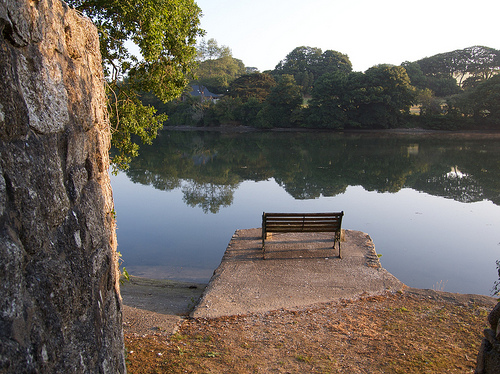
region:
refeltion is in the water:
[255, 146, 475, 208]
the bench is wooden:
[253, 206, 360, 266]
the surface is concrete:
[235, 261, 371, 296]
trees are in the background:
[283, 63, 398, 123]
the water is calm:
[285, 140, 430, 222]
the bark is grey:
[35, 105, 111, 340]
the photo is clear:
[2, 11, 482, 352]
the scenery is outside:
[2, 5, 487, 367]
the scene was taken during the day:
[6, 5, 476, 366]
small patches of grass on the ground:
[292, 312, 418, 359]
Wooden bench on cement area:
[258, 208, 345, 258]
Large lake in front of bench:
[114, 130, 498, 290]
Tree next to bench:
[68, 0, 202, 173]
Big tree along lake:
[264, 73, 306, 120]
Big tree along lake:
[310, 73, 351, 105]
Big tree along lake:
[345, 70, 385, 101]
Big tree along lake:
[368, 62, 415, 114]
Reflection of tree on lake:
[180, 127, 238, 210]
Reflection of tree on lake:
[440, 171, 487, 201]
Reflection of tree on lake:
[147, 132, 179, 189]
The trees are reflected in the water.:
[121, 39, 496, 211]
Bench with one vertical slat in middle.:
[259, 210, 344, 257]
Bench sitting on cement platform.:
[186, 211, 406, 317]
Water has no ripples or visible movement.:
[110, 123, 498, 302]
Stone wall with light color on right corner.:
[5, 2, 127, 372]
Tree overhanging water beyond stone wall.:
[68, 0, 206, 172]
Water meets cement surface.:
[110, 265, 212, 295]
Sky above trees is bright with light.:
[89, 1, 498, 76]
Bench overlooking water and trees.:
[112, 0, 499, 257]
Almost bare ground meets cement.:
[121, 288, 496, 370]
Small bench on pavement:
[255, 202, 352, 271]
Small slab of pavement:
[188, 204, 400, 330]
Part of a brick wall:
[1, 48, 140, 373]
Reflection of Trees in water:
[244, 127, 329, 204]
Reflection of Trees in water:
[341, 131, 411, 216]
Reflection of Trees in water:
[421, 135, 494, 198]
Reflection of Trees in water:
[185, 130, 237, 207]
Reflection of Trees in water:
[232, 127, 275, 197]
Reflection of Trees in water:
[102, 131, 189, 213]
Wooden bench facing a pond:
[259, 209, 345, 256]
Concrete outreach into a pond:
[188, 225, 398, 322]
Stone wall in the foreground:
[2, 0, 127, 370]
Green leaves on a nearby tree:
[82, 0, 202, 175]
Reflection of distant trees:
[117, 128, 475, 212]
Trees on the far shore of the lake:
[115, 42, 474, 136]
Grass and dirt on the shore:
[123, 290, 475, 372]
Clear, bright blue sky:
[200, 0, 497, 67]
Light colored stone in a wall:
[16, 53, 71, 135]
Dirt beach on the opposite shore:
[161, 125, 498, 135]